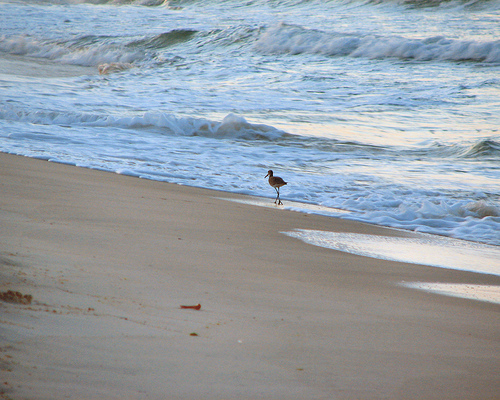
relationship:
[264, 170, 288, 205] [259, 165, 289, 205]
bird on beach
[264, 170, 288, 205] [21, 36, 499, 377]
bird standing on beach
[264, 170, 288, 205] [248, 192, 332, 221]
bird standing in wet patch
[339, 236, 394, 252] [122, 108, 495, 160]
sand receding from wave